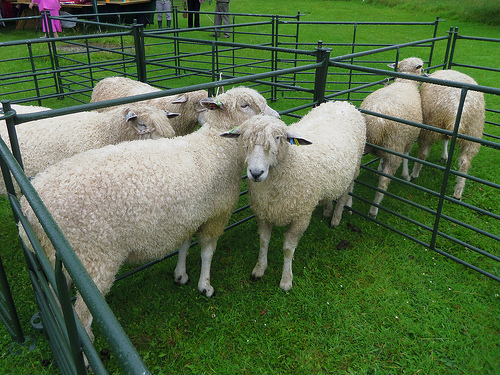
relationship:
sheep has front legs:
[228, 99, 366, 288] [251, 214, 301, 294]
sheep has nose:
[228, 99, 366, 288] [250, 167, 263, 177]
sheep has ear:
[228, 99, 366, 288] [283, 135, 312, 145]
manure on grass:
[335, 216, 362, 251] [5, 1, 500, 373]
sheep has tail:
[360, 59, 424, 218] [368, 115, 385, 148]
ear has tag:
[283, 135, 312, 145] [294, 139, 298, 145]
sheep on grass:
[228, 99, 366, 288] [5, 1, 500, 373]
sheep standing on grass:
[360, 59, 424, 218] [5, 1, 500, 373]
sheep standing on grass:
[421, 69, 480, 198] [5, 1, 500, 373]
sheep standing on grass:
[21, 85, 283, 318] [5, 1, 500, 373]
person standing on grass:
[29, 2, 69, 39] [5, 1, 500, 373]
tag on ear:
[294, 139, 298, 145] [283, 135, 312, 145]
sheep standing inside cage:
[228, 99, 366, 288] [3, 10, 498, 371]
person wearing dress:
[29, 2, 69, 39] [36, 3, 65, 29]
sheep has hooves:
[228, 99, 366, 288] [251, 269, 267, 280]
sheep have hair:
[228, 99, 366, 288] [245, 118, 287, 158]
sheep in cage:
[228, 99, 366, 288] [3, 10, 498, 371]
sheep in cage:
[421, 69, 480, 198] [3, 10, 498, 371]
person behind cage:
[29, 2, 69, 39] [3, 10, 498, 371]